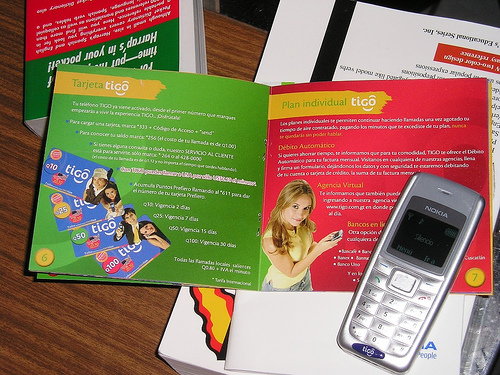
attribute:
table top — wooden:
[2, 281, 172, 368]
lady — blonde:
[259, 168, 334, 290]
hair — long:
[257, 167, 315, 249]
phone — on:
[386, 206, 447, 268]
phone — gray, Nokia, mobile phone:
[332, 169, 486, 373]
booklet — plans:
[26, 61, 494, 296]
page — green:
[15, 54, 270, 307]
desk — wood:
[2, 1, 499, 363]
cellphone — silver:
[324, 155, 495, 374]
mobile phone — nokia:
[325, 175, 467, 359]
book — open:
[25, 73, 493, 293]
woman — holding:
[260, 179, 344, 289]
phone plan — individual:
[31, 68, 271, 281]